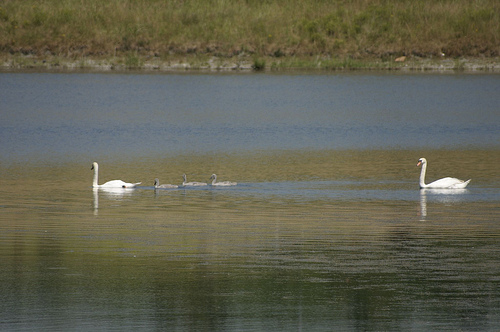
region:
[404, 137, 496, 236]
swan on the water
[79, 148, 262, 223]
mama swan with three babies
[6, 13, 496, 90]
bank of the pond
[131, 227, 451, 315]
reflections in the water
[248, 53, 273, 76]
green bush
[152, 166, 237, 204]
three gray baby swans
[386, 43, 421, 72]
animal on the bank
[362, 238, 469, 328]
ripples on the water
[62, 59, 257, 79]
sand on the bank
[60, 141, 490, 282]
swan family on the water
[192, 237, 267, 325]
the water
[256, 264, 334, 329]
the water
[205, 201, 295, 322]
the water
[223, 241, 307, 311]
the water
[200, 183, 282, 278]
the water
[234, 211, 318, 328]
the water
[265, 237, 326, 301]
the water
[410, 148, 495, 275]
the swan is white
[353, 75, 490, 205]
the swan is white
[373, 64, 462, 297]
the swan is white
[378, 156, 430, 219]
the swan is white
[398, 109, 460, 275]
the swan is white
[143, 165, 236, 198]
three small swans in the water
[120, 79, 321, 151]
calm blue lake water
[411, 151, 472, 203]
swan swimming in the lake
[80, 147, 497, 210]
five white swans in the water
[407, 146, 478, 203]
white bird with long neck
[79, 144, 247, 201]
four birds in a row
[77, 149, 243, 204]
one big bird and three small birds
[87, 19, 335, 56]
clumps of dirt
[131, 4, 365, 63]
grass growing by lake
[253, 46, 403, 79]
green grass by water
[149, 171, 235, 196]
three baby ducks in a row